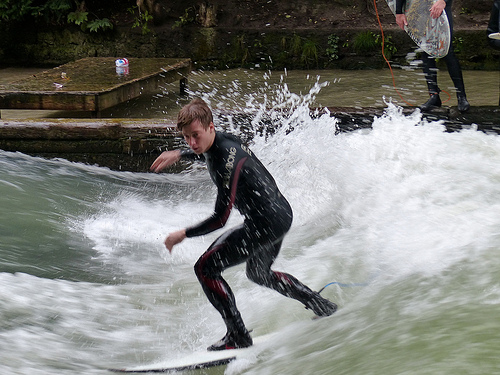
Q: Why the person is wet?
A: He is in the water.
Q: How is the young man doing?
A: Balancing.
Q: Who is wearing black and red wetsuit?
A: Surfer.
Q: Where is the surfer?
A: Water.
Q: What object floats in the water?
A: Surfboard.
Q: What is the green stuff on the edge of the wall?
A: Moss.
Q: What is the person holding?
A: Surfboard.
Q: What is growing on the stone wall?
A: Plants.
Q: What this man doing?
A: Surfing.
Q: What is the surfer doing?
A: Surfing.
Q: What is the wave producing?
A: White foam.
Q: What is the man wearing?
A: A wetsuit.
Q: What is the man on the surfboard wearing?
A: A wet suit.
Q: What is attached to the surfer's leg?
A: A leg rope.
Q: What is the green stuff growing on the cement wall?
A: Moss.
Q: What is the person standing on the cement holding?
A: A surf board.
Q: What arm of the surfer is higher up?
A: His right arm.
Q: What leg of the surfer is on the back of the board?
A: The right leg.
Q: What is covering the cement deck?
A: Water.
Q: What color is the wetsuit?
A: Black.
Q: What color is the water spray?
A: White.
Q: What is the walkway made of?
A: Concrete.